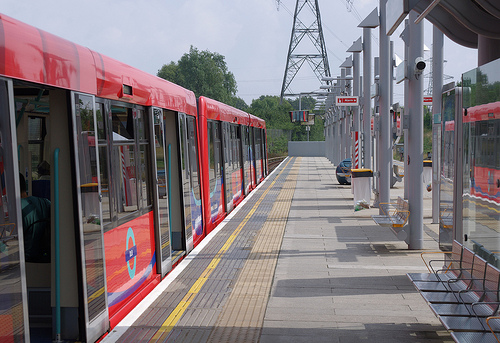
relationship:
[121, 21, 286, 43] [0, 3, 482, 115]
clouds in sky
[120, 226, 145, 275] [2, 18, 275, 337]
graphic on train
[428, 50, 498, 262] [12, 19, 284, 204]
reflection of train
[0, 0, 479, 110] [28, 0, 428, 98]
clouds in sky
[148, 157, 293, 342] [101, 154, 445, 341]
line on platform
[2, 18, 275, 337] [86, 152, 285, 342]
train on track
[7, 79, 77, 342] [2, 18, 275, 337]
door on train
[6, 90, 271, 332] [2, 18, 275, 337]
window on train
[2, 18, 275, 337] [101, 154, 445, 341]
train on platform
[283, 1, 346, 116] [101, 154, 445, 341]
tower at end of platform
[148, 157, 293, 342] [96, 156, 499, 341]
line on platform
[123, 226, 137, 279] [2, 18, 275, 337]
graphic on train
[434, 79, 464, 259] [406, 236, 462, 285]
display behind seat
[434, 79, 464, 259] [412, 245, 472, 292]
display behind seat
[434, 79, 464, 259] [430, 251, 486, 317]
display behind seat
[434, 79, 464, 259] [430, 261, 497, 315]
display behind seat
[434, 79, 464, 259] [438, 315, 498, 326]
display behind seat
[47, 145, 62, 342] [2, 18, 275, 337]
pole on train